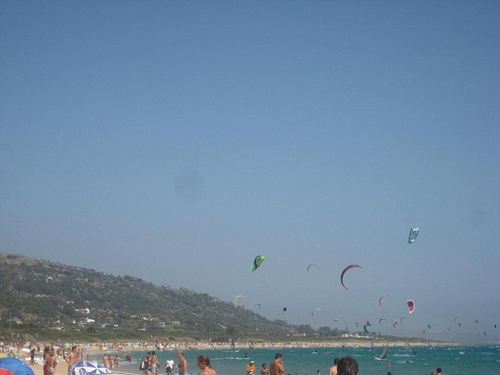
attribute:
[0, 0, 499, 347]
sky — blue, large, dark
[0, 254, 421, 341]
hill — grassy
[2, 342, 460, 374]
beach — sandy, sloped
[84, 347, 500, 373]
water — blue, green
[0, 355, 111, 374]
umbrellas — blue, white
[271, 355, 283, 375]
man — shirtless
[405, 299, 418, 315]
parasail — flying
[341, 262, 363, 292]
kite — red, crescent shaped, large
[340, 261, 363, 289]
kite — moon shaped, large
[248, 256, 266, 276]
kite — green, large, blue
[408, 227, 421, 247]
kite — silver, rectangle, large, blue, white, highest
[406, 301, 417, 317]
kite — red, white, large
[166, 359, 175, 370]
shirt — white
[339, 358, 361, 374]
hair — dark